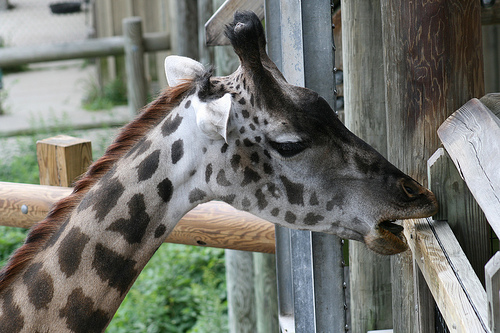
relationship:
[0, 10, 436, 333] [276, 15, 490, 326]
giraffe near fence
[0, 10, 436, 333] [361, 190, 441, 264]
giraffe with mouth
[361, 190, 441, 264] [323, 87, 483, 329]
mouth on fence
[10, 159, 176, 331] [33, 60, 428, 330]
neck of giraffe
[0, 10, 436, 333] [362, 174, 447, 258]
giraffe with mouth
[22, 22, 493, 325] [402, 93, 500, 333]
giraffe about to bite a fence